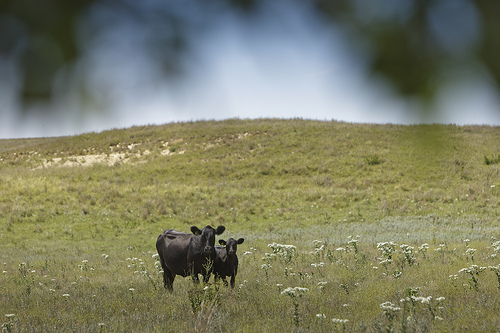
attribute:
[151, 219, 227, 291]
cow — standing, black, large, mother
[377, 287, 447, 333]
flowers — white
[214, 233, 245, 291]
cow — child, black, small, baby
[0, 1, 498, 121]
vegetation — blurred, blue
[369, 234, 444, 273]
flowers — white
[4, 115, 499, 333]
field — barren, tall, grassy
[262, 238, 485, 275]
plant — white, green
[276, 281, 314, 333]
plant — white, green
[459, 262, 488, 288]
plant — white, green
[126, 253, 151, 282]
plant — white, green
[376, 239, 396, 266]
plant — white, green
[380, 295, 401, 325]
plant — white, green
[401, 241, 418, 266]
plant — white, green